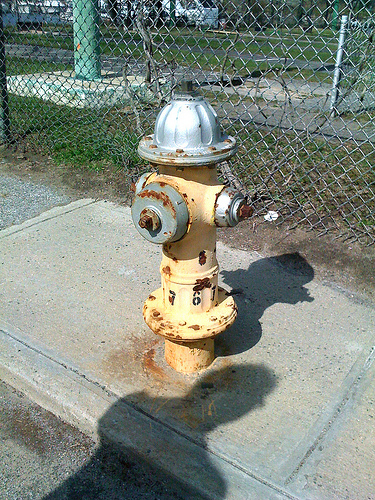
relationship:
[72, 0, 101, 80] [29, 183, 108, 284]
pole mounted in concrete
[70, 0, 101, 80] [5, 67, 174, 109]
pole mounted in base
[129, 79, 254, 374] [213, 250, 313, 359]
fire hydrant casts shadow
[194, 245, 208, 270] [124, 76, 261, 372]
rust visible on fire hydrant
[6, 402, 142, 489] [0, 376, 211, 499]
gravel on side of road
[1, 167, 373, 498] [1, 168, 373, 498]
gravel strewn on sidewalk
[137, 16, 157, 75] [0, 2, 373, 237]
vine growing on fence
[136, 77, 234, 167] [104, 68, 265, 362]
top part of hydrant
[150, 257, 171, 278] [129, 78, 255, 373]
rust visible on hydrant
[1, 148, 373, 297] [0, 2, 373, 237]
dirt along fence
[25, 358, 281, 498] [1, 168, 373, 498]
shadow visible on sidewalk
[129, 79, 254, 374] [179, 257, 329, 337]
fire hydrant casts shadow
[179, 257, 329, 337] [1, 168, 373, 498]
shadow visible on sidewalk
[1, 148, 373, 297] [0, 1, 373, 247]
dirt at base of chainlink fence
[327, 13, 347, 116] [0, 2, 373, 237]
post behind fence